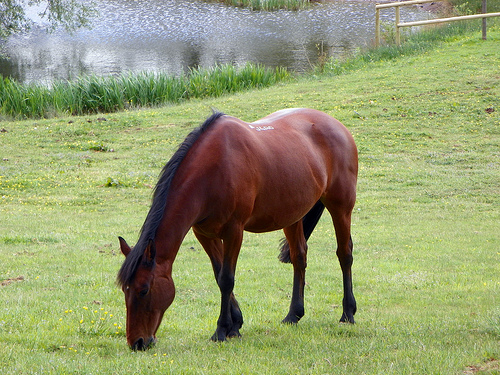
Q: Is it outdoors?
A: Yes, it is outdoors.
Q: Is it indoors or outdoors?
A: It is outdoors.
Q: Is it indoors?
A: No, it is outdoors.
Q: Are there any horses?
A: Yes, there is a horse.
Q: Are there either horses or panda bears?
A: Yes, there is a horse.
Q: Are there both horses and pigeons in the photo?
A: No, there is a horse but no pigeons.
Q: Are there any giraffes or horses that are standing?
A: Yes, the horse is standing.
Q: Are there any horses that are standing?
A: Yes, there is a horse that is standing.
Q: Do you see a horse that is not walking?
A: Yes, there is a horse that is standing .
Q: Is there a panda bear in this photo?
A: No, there are no panda bears.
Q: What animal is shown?
A: The animal is a horse.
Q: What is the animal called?
A: The animal is a horse.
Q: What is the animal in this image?
A: The animal is a horse.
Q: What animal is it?
A: The animal is a horse.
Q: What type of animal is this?
A: This is a horse.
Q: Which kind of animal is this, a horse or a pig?
A: This is a horse.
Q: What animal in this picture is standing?
A: The animal is a horse.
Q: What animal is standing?
A: The animal is a horse.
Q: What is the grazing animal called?
A: The animal is a horse.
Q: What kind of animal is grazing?
A: The animal is a horse.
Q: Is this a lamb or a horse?
A: This is a horse.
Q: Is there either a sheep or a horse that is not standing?
A: No, there is a horse but it is standing.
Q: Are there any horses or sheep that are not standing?
A: No, there is a horse but it is standing.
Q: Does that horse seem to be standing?
A: Yes, the horse is standing.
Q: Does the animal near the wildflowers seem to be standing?
A: Yes, the horse is standing.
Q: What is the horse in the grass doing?
A: The horse is standing.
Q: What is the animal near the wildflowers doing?
A: The horse is standing.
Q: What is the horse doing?
A: The horse is standing.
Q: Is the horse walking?
A: No, the horse is standing.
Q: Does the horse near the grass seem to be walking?
A: No, the horse is standing.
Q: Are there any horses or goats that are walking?
A: No, there is a horse but it is standing.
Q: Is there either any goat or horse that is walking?
A: No, there is a horse but it is standing.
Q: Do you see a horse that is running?
A: No, there is a horse but it is standing.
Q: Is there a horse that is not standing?
A: No, there is a horse but it is standing.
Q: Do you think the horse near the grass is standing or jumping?
A: The horse is standing.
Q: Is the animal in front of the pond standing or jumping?
A: The horse is standing.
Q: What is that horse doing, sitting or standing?
A: The horse is standing.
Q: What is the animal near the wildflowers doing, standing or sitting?
A: The horse is standing.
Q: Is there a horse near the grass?
A: Yes, there is a horse near the grass.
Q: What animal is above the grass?
A: The animal is a horse.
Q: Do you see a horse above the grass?
A: Yes, there is a horse above the grass.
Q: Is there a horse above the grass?
A: Yes, there is a horse above the grass.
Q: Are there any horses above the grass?
A: Yes, there is a horse above the grass.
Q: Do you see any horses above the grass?
A: Yes, there is a horse above the grass.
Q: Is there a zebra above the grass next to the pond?
A: No, there is a horse above the grass.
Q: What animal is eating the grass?
A: The horse is eating the grass.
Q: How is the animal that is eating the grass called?
A: The animal is a horse.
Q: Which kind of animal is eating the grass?
A: The animal is a horse.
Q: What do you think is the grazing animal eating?
A: The horse is eating grass.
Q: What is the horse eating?
A: The horse is eating grass.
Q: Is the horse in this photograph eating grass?
A: Yes, the horse is eating grass.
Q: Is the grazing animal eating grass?
A: Yes, the horse is eating grass.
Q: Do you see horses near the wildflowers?
A: Yes, there is a horse near the wildflowers.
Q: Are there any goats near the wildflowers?
A: No, there is a horse near the wildflowers.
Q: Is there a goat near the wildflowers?
A: No, there is a horse near the wildflowers.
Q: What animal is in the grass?
A: The animal is a horse.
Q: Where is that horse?
A: The horse is in the grass.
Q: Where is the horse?
A: The horse is in the grass.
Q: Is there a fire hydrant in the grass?
A: No, there is a horse in the grass.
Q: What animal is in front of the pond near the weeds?
A: The horse is in front of the pond.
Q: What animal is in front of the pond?
A: The horse is in front of the pond.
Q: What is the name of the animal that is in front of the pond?
A: The animal is a horse.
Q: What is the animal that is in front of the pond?
A: The animal is a horse.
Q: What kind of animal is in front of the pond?
A: The animal is a horse.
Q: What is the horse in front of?
A: The horse is in front of the pond.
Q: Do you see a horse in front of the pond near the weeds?
A: Yes, there is a horse in front of the pond.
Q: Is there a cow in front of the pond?
A: No, there is a horse in front of the pond.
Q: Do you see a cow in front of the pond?
A: No, there is a horse in front of the pond.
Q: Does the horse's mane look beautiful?
A: Yes, the mane is beautiful.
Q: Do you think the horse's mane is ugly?
A: No, the mane is beautiful.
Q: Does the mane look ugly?
A: No, the mane is beautiful.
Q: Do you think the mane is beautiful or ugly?
A: The mane is beautiful.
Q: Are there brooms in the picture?
A: No, there are no brooms.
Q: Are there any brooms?
A: No, there are no brooms.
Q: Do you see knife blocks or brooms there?
A: No, there are no brooms or knife blocks.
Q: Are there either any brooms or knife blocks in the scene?
A: No, there are no brooms or knife blocks.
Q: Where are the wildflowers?
A: The wildflowers are on the grass.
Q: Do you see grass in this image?
A: Yes, there is grass.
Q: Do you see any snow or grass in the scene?
A: Yes, there is grass.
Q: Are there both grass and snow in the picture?
A: No, there is grass but no snow.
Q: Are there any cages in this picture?
A: No, there are no cages.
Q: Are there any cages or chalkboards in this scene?
A: No, there are no cages or chalkboards.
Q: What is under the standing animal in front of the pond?
A: The grass is under the horse.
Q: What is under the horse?
A: The grass is under the horse.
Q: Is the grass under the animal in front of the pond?
A: Yes, the grass is under the horse.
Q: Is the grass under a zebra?
A: No, the grass is under the horse.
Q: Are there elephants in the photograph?
A: No, there are no elephants.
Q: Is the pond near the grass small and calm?
A: Yes, the pond is small and calm.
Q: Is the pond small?
A: Yes, the pond is small.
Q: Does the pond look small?
A: Yes, the pond is small.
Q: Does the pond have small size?
A: Yes, the pond is small.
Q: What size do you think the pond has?
A: The pond has small size.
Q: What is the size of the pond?
A: The pond is small.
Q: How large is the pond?
A: The pond is small.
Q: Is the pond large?
A: No, the pond is small.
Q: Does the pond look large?
A: No, the pond is small.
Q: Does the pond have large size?
A: No, the pond is small.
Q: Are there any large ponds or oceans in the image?
A: No, there is a pond but it is small.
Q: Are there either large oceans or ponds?
A: No, there is a pond but it is small.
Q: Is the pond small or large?
A: The pond is small.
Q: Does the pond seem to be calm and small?
A: Yes, the pond is calm and small.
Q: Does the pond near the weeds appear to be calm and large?
A: No, the pond is calm but small.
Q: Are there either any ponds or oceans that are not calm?
A: No, there is a pond but it is calm.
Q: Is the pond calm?
A: Yes, the pond is calm.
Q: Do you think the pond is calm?
A: Yes, the pond is calm.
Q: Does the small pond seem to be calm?
A: Yes, the pond is calm.